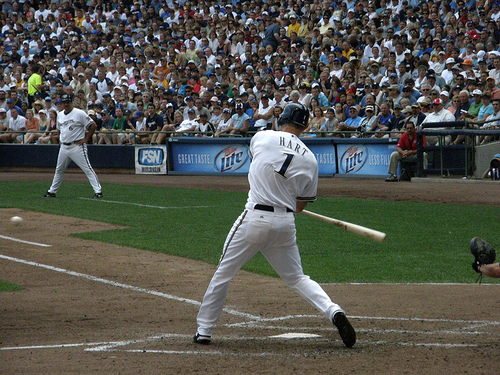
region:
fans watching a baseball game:
[16, 55, 427, 340]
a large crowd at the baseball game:
[4, 5, 493, 210]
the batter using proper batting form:
[175, 82, 422, 372]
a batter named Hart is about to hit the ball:
[5, 99, 415, 346]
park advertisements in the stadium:
[22, 111, 489, 206]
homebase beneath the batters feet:
[108, 261, 435, 366]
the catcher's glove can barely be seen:
[445, 220, 498, 292]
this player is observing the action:
[18, 85, 143, 230]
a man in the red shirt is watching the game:
[366, 92, 451, 199]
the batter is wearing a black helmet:
[168, 67, 359, 148]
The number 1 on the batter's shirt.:
[278, 149, 296, 179]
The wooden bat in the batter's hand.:
[303, 204, 400, 246]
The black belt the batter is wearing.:
[247, 202, 292, 219]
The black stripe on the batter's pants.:
[199, 212, 247, 272]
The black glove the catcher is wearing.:
[468, 234, 498, 276]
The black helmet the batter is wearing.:
[272, 102, 312, 129]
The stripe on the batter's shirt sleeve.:
[296, 192, 318, 204]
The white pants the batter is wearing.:
[223, 198, 337, 337]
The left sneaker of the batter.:
[184, 315, 221, 352]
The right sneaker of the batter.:
[324, 312, 363, 344]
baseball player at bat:
[223, 98, 393, 341]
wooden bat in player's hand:
[295, 202, 387, 247]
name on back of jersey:
[268, 132, 303, 157]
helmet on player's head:
[275, 102, 310, 134]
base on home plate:
[266, 324, 315, 350]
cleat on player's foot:
[178, 318, 224, 350]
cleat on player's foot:
[326, 299, 359, 357]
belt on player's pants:
[243, 195, 291, 217]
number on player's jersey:
[266, 154, 301, 186]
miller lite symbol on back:
[338, 147, 378, 172]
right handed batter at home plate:
[176, 93, 391, 353]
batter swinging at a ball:
[169, 84, 406, 354]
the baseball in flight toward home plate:
[1, 199, 38, 239]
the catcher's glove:
[459, 225, 499, 282]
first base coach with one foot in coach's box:
[28, 80, 113, 210]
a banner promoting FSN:
[125, 137, 171, 177]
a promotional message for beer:
[165, 137, 255, 177]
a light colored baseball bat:
[300, 207, 386, 242]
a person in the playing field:
[377, 120, 423, 190]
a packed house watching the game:
[5, 0, 480, 131]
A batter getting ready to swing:
[172, 62, 432, 357]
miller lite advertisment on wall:
[166, 134, 411, 187]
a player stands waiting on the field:
[34, 89, 122, 214]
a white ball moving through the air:
[11, 208, 26, 230]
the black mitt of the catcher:
[463, 229, 499, 276]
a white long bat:
[288, 195, 410, 247]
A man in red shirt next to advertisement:
[369, 114, 440, 186]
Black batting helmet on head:
[273, 96, 327, 136]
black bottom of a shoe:
[333, 308, 365, 351]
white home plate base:
[268, 319, 315, 348]